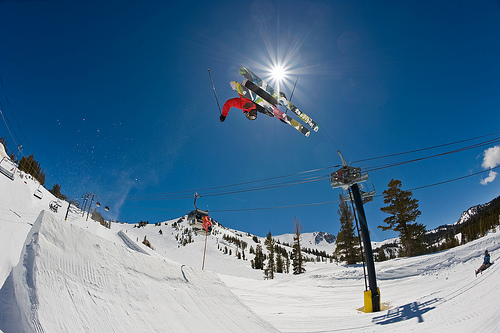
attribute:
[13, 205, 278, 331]
half pipe — snowboard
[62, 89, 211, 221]
cloud — white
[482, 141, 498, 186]
cloud — white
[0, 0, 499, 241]
sky — blue, clear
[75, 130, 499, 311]
ski lift — pictured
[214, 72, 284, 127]
person — doing trick, airborne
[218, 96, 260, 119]
jacket — red, ski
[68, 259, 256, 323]
snow — white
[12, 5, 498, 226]
sky — blue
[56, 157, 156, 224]
cloud — white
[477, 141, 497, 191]
cloud — white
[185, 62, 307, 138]
skier — airborne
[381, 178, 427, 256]
tree — distant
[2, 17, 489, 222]
sky — blue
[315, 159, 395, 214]
ski lift — car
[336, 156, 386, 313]
pole — support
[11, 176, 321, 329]
facility — outdoor, winter sport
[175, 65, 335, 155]
skier — stunt-performing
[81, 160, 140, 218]
cloud — white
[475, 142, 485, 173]
cloud — white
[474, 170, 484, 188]
cloud — white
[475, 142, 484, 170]
cloud — white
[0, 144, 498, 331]
ground — snow-covered